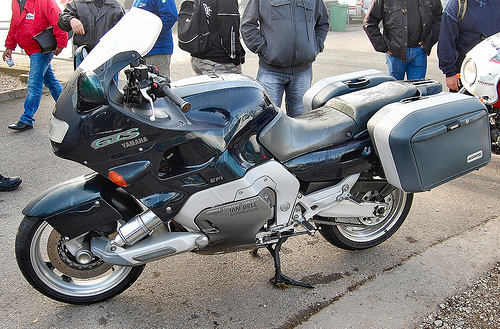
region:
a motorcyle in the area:
[50, 36, 475, 287]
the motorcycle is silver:
[22, 40, 497, 308]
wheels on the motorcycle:
[13, 176, 419, 309]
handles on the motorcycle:
[125, 59, 192, 124]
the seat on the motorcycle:
[273, 80, 415, 146]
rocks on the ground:
[438, 279, 497, 324]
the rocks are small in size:
[428, 263, 499, 325]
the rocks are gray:
[431, 273, 498, 328]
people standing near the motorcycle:
[8, 7, 490, 189]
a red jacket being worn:
[1, 0, 71, 60]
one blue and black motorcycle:
[13, 21, 489, 308]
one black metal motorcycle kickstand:
[258, 239, 321, 297]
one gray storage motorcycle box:
[366, 84, 491, 196]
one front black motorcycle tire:
[13, 190, 151, 310]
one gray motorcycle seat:
[270, 99, 360, 157]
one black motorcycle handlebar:
[160, 80, 194, 114]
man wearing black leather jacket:
[241, 3, 334, 74]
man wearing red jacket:
[1, 0, 71, 69]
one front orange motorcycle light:
[102, 166, 136, 189]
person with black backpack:
[173, 0, 247, 70]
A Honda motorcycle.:
[457, 29, 499, 155]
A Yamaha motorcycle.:
[13, 9, 491, 304]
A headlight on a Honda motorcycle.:
[461, 56, 478, 85]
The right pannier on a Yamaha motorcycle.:
[367, 91, 490, 192]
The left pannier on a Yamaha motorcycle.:
[301, 68, 397, 110]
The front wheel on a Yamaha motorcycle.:
[14, 191, 145, 306]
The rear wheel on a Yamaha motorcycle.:
[315, 178, 414, 250]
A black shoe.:
[0, 174, 23, 193]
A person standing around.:
[238, 1, 330, 118]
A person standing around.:
[362, 0, 447, 81]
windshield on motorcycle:
[75, 7, 185, 131]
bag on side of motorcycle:
[354, 102, 499, 182]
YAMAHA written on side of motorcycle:
[112, 134, 162, 160]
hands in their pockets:
[235, 28, 349, 65]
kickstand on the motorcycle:
[242, 224, 324, 308]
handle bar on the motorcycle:
[134, 81, 204, 122]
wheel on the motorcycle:
[9, 172, 149, 305]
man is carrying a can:
[1, 46, 18, 71]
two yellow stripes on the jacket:
[450, 2, 470, 22]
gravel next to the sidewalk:
[423, 265, 491, 323]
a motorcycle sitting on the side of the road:
[26, 17, 496, 304]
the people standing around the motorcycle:
[6, 3, 498, 113]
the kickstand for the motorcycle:
[263, 239, 295, 292]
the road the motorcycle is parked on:
[4, 70, 499, 325]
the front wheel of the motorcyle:
[11, 210, 151, 307]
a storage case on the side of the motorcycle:
[366, 90, 496, 188]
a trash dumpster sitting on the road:
[325, 3, 350, 33]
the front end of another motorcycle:
[451, 31, 498, 111]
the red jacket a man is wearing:
[6, 5, 61, 52]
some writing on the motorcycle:
[87, 131, 147, 163]